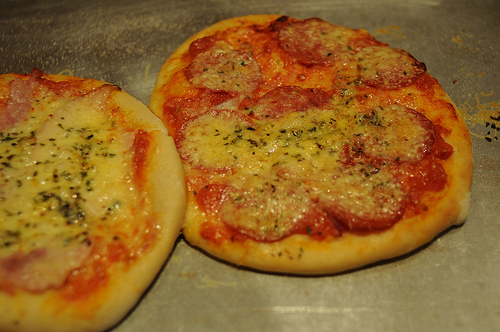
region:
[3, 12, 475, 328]
Mini pizzas are shown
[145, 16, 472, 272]
Pizza on right is pepperoni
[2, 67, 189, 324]
Pizza has Canadian Bacon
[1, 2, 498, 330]
Food is on metal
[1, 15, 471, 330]
Two pizzas are shown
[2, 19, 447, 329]
Cheese is melted on top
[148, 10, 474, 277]
Crust is golden brown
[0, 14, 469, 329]
Pizza has seasonings on top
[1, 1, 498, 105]
Crumbs are left behind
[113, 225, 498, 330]
Metal is reflective surface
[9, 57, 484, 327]
two pizzas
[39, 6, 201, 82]
silver baking pan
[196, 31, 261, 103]
pepperoni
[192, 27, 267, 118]
pepperoni with cheese on it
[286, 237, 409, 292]
pizza crust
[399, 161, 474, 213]
tomato sauce underneath pepperoni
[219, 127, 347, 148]
green herbs on top of cheese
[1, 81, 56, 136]
ham on pizza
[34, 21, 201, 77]
tan colored crumbs on pan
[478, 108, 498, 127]
black spots on pizza pan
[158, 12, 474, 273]
A small cooked pizza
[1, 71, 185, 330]
Half of a small cooked pizza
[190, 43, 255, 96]
A piece of pepperoni covered in cheese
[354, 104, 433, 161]
A piece of pepperoni covered in cheese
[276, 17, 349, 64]
A piece of pepperoni covered in cheese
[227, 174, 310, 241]
A piece of pepperoni covered in cheese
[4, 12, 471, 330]
Two small pizzas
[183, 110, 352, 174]
A dense portion of cheese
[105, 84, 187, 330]
The crust of the pizza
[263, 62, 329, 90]
Pizza sauce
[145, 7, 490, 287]
Pizza on a surface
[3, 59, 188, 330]
Cheese pizza on a surface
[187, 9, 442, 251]
Pizza has slices of tomatoes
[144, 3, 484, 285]
Pizza has cheese on top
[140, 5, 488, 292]
Pizza is covered with tomato sauce under tomato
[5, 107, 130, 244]
Melted cheese on pizza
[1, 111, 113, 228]
herbs on top of cheese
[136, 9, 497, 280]
Crust of pizza is brown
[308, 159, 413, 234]
Slice of tomato cover with cheese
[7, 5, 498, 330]
Surface is brown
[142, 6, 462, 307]
the dough is cooked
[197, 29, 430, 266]
pepperoni on top of pizza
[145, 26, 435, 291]
the cheese is yellow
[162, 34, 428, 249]
the cheese on top of the pepperoni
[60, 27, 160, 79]
the pan is silver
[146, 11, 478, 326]
pizza on top of the pan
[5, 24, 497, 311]
there are two pizzas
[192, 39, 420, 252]
tomato sauce is red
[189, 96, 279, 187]
the pepperoni is red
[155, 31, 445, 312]
the dough is beige